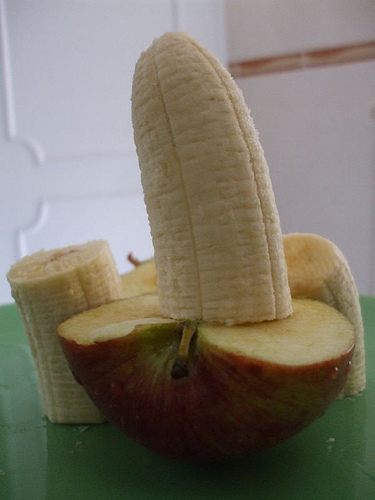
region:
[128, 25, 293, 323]
long piece of banana on top of an apple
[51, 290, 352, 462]
half an apple with a banana on top of it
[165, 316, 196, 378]
stem of apple with a banana on it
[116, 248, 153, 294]
apple halve in the background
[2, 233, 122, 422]
banana piece on the left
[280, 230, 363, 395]
banana on the right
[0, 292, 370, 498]
shiny green counter top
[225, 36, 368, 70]
red and yellow wall decoration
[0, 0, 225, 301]
white paneled wall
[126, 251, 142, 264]
stem of the apple in the background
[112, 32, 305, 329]
A piece of banana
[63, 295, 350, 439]
An apple cut in half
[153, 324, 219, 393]
Brown stem of an apple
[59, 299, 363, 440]
The apple is red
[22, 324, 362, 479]
The counter is green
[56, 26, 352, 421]
The banana is stacked strategically on top of the sliced apple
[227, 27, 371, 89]
Orange sign on the wall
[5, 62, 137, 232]
White wall behind table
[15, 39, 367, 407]
The bananas are peeled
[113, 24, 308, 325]
The piece of banana points up towards the sky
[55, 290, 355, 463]
red apple is cut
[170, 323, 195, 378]
yellow apple stem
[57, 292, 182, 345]
apple flesh is white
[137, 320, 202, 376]
green ring around stem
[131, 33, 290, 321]
banana on top of apple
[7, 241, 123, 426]
banana next to apple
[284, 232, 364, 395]
banana behind apple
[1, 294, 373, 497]
green table under apple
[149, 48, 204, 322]
line down side of banana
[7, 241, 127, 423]
banana on green table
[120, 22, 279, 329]
Half of a banana.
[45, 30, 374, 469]
The banana is standing on top of the apple.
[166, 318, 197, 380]
The stem on the animal.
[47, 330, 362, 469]
The apple skin is red and green.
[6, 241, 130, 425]
A section of a banana.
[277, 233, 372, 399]
Another section of the banana.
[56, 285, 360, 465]
The apple is cut in half.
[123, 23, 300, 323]
The banana is light yellow.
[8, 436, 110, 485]
The table is green.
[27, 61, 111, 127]
The wall is white.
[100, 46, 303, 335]
banana is on apple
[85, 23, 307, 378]
banana is cut in half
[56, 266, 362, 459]
the apple is red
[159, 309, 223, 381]
stem on apple is brown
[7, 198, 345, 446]
bananas behind the apple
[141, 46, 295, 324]
lines in the banana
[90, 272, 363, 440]
apple is cut in half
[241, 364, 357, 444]
green color on apple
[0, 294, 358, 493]
the counter is green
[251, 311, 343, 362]
brown coloring on apple